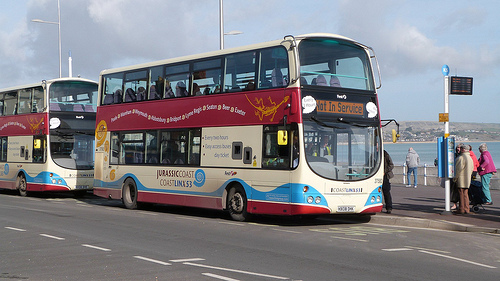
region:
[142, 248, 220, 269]
lines in the street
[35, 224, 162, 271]
white color on the lines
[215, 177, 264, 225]
large black wheels on the bus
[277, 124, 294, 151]
yellow mirror on side of the bus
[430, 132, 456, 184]
blue sign on the post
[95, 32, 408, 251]
large bus on the street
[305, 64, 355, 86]
seats in the bus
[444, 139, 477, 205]
man standing on the street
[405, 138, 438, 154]
blue water in the lake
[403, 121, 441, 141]
houses on the shore line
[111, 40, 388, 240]
bus has second deck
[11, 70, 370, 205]
two busses parked along road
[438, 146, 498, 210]
people waitng for the bus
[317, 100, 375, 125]
sign out of service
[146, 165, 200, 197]
name of company that owns bus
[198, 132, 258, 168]
advertisement on the side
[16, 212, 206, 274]
white marking on the road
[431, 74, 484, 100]
sign on the pole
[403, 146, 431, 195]
person with gray hood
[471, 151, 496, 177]
lady with pink jacket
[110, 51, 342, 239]
red white and blue bus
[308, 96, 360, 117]
orange LCD screen on bus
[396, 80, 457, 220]
blue and white pole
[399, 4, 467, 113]
blue and white sky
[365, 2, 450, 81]
white and puffy clouds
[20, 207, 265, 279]
white lines on road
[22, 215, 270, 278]
road is dark grey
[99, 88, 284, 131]
red stripe on bus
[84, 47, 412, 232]
bus is double decker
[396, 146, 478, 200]
people are outside bus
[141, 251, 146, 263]
part of a line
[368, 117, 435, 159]
prt of a mirror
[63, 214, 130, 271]
psrt of a line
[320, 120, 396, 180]
part of a window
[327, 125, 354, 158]
part of a glass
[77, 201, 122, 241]
part of a road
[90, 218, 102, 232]
art pf a raod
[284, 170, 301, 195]
edge of a bus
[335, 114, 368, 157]
part of a window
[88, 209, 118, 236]
part of a road